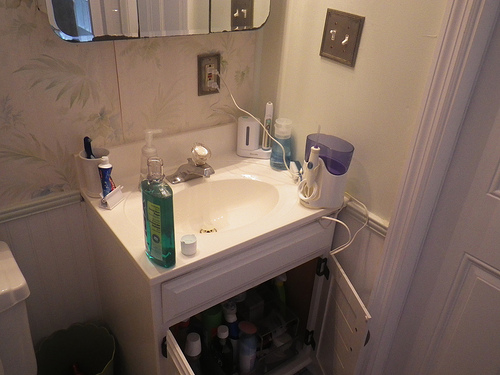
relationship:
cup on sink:
[80, 149, 109, 199] [147, 172, 293, 246]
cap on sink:
[179, 230, 196, 258] [147, 172, 293, 246]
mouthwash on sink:
[139, 178, 181, 265] [147, 172, 293, 246]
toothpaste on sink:
[98, 156, 126, 211] [147, 172, 293, 246]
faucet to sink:
[167, 144, 225, 186] [147, 172, 293, 246]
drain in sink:
[199, 215, 216, 236] [147, 172, 293, 246]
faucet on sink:
[167, 144, 225, 186] [147, 172, 293, 246]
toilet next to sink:
[1, 239, 42, 375] [147, 172, 293, 246]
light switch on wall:
[318, 8, 364, 67] [262, 2, 457, 226]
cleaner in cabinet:
[271, 277, 292, 307] [167, 242, 335, 374]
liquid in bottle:
[271, 146, 292, 166] [271, 119, 295, 170]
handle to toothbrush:
[302, 147, 324, 206] [296, 118, 324, 205]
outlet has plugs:
[201, 51, 230, 102] [208, 65, 216, 93]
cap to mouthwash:
[179, 230, 196, 258] [139, 178, 181, 265]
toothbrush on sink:
[296, 118, 324, 205] [147, 172, 293, 246]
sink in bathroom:
[147, 172, 293, 246] [2, 1, 499, 375]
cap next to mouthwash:
[179, 230, 196, 258] [139, 178, 181, 265]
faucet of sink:
[167, 144, 225, 186] [147, 172, 293, 246]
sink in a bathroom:
[147, 172, 293, 246] [2, 1, 499, 375]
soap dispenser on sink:
[140, 125, 162, 179] [147, 172, 293, 246]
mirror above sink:
[50, 3, 276, 43] [147, 172, 293, 246]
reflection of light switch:
[227, 3, 265, 28] [318, 8, 364, 67]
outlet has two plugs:
[201, 51, 230, 102] [208, 65, 216, 93]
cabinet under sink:
[167, 242, 335, 374] [147, 172, 293, 246]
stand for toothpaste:
[94, 190, 131, 210] [98, 156, 126, 211]